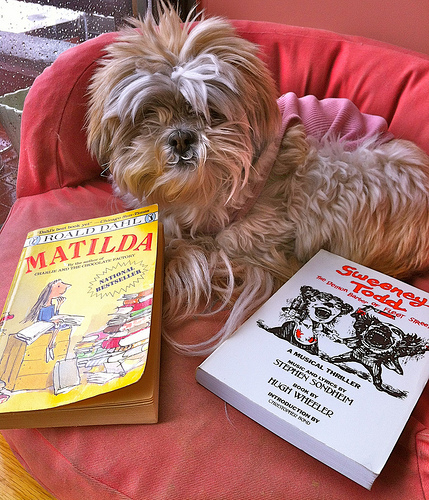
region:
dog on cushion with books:
[75, 16, 426, 275]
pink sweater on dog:
[275, 86, 390, 147]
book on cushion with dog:
[16, 220, 169, 417]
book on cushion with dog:
[224, 246, 417, 443]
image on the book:
[277, 281, 406, 372]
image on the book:
[13, 272, 126, 365]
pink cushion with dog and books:
[17, 18, 418, 497]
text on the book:
[262, 347, 361, 424]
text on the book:
[29, 236, 155, 267]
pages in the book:
[151, 276, 165, 422]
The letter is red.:
[24, 250, 48, 275]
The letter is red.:
[47, 243, 69, 268]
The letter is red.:
[67, 238, 88, 263]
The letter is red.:
[87, 235, 100, 257]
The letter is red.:
[96, 232, 115, 255]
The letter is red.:
[116, 231, 138, 254]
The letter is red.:
[134, 226, 154, 254]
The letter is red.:
[328, 258, 355, 276]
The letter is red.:
[348, 277, 370, 294]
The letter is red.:
[387, 295, 407, 312]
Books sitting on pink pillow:
[1, 203, 422, 491]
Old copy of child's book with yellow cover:
[0, 203, 162, 430]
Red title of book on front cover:
[22, 228, 151, 275]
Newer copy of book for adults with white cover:
[195, 245, 427, 490]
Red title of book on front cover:
[315, 261, 428, 327]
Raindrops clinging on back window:
[5, 3, 133, 56]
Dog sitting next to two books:
[3, 2, 427, 489]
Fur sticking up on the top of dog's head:
[87, 7, 270, 86]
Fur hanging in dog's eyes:
[134, 76, 224, 127]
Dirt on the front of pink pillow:
[6, 309, 426, 497]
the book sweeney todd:
[197, 209, 428, 495]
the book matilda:
[4, 222, 159, 427]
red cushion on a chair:
[168, 450, 224, 481]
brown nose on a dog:
[164, 128, 197, 156]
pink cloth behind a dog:
[260, 82, 391, 162]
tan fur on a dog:
[253, 168, 319, 221]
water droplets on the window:
[27, 11, 63, 37]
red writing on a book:
[30, 231, 150, 270]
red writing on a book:
[335, 263, 426, 318]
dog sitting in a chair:
[74, 7, 428, 341]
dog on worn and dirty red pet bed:
[11, 4, 422, 489]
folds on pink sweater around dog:
[224, 89, 379, 221]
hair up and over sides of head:
[84, 7, 274, 139]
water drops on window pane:
[0, 0, 123, 212]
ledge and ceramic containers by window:
[0, 26, 78, 221]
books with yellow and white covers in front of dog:
[0, 197, 421, 478]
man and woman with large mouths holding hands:
[251, 268, 420, 398]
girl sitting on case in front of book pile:
[3, 272, 144, 383]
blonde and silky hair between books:
[166, 241, 266, 349]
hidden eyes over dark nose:
[125, 99, 222, 150]